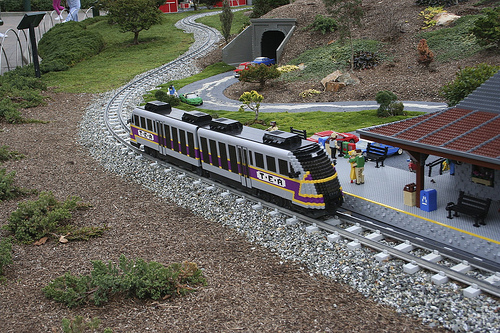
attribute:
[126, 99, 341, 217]
model train — small   , model   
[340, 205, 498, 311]
tracks — white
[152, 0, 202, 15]
building — red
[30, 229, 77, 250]
leaves — yellow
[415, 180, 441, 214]
trash can — blue  , white  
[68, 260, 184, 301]
bush — large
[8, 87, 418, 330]
brown dirt — brown 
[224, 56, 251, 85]
car — red 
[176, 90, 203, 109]
car — green 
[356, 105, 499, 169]
overhang — brown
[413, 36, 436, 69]
bush — brown 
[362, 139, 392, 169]
bench — black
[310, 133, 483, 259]
platform — train